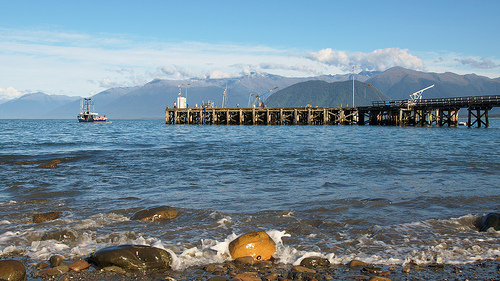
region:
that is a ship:
[61, 90, 106, 133]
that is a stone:
[231, 223, 281, 262]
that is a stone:
[135, 195, 182, 231]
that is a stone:
[31, 198, 66, 226]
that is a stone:
[96, 243, 170, 269]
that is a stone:
[64, 254, 90, 279]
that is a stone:
[3, 256, 32, 279]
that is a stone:
[306, 252, 327, 279]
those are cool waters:
[289, 146, 334, 174]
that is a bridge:
[170, 106, 457, 123]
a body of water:
[104, 150, 236, 212]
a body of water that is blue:
[178, 136, 363, 278]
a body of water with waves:
[84, 125, 244, 234]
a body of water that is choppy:
[154, 121, 374, 268]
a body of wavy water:
[148, 129, 332, 229]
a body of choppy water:
[149, 103, 367, 250]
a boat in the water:
[32, 73, 128, 136]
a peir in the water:
[218, 76, 367, 141]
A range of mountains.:
[83, 62, 496, 85]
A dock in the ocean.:
[164, 85, 499, 127]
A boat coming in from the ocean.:
[76, 95, 107, 122]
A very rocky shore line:
[1, 156, 499, 279]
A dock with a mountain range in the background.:
[3, 64, 498, 133]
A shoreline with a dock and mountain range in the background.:
[3, 43, 498, 274]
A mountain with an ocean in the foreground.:
[1, 85, 73, 133]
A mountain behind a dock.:
[261, 79, 391, 125]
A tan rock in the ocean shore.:
[228, 229, 277, 261]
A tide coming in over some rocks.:
[31, 203, 401, 280]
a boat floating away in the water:
[74, 93, 105, 122]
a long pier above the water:
[163, 97, 499, 130]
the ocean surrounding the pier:
[3, 119, 498, 268]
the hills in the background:
[4, 73, 498, 116]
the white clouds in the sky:
[6, 37, 498, 77]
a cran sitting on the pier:
[405, 81, 442, 106]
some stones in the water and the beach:
[6, 201, 423, 276]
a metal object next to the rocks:
[220, 227, 276, 258]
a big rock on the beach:
[93, 240, 168, 273]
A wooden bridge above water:
[164, 95, 499, 127]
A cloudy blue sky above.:
[0, 0, 499, 103]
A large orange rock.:
[227, 229, 281, 261]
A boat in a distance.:
[75, 95, 108, 122]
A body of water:
[0, 117, 499, 264]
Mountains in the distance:
[0, 66, 498, 116]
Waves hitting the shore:
[0, 197, 498, 265]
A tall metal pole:
[351, 63, 356, 105]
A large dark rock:
[92, 242, 172, 274]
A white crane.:
[409, 81, 436, 97]